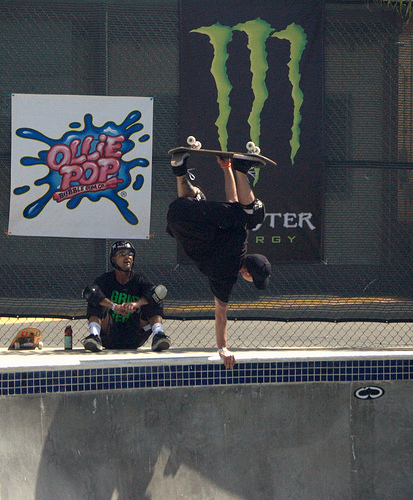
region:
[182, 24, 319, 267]
large Monster energy drink logo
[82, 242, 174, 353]
young man sitting down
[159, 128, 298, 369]
young man upsid down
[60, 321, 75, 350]
plastic drink bottole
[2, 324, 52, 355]
skateboard hanging on by its front wheels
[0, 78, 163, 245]
Ollie Pop bubble gum sign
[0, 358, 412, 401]
dark blue tile along the top of the concrete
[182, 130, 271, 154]
four tiny white wheels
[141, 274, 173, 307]
bulky elbow pad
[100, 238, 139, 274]
black helmet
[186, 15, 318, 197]
The letter is green.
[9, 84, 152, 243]
The sign is white.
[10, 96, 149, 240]
The sign is blue and red.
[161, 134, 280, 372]
The man is skateboarding.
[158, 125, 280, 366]
He is doing a trick.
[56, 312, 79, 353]
The juice is on the ground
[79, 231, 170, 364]
The man is sitting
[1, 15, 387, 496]
They are at a skate park.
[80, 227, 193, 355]
He is wearing a helmet.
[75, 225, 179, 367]
He is wearing pads.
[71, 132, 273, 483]
skateboarders at an empty poll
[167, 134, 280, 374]
skateboarder with one hand on the side of the pool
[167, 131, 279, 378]
the skateboarder is upside down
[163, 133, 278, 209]
both feet are on the skateboard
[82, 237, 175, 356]
a skateboarder sitting on the side of the pool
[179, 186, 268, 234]
the skateboarder has knee pads on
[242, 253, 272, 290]
the boy is wearing a black cap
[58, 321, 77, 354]
a bottle of soda is by the pool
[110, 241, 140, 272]
the boy is wearing glasses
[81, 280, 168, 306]
the boy is wearing arm pads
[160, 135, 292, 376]
a skateboarder holding himself on one hand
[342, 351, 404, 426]
water drain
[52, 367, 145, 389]
blue and white tiles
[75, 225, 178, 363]
a man sitting down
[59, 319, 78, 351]
a bottle of juice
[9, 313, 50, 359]
a skateboard propped up on the edge of a pool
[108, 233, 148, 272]
man wearing a black helmet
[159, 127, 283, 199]
man holding a skateboard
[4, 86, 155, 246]
an advertisement for bubble gum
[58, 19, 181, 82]
a metallic fence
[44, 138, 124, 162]
The word Ollie on the sign.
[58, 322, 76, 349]
The drink on the left of the skater sitting down.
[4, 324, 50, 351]
The skateboard next to the chain linked fence.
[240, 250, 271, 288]
The black baseball hat the skater in the air is wearing.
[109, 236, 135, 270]
The black helmet the skater sitting down is wearing.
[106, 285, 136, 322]
The green design on the shirt of the skater who is sitting.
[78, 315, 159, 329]
The white socks the skater who is sitting down is wearing.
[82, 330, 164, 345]
The sneakers the skater who is sitting down is wearing.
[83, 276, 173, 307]
The elbow pads on the skater who is sitting down.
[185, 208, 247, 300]
The black t-shirt the skater that is doing the trick is wearing.